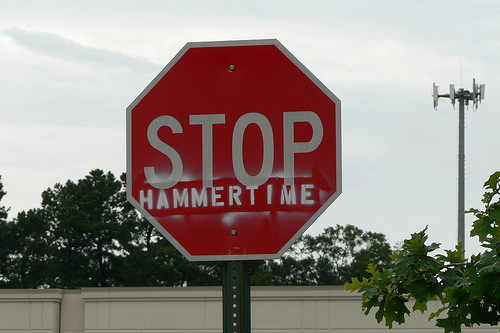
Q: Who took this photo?
A: Person.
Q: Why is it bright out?
A: Daytime.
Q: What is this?
A: Sign.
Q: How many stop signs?
A: 1.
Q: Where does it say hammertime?
A: Below stop.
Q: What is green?
A: Trees.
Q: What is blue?
A: Sky.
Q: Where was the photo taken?
A: At an intersection.